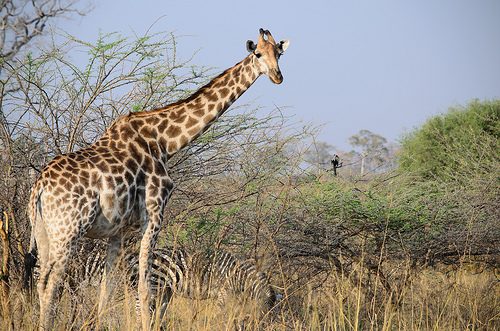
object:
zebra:
[123, 246, 282, 331]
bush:
[0, 181, 26, 290]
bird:
[331, 153, 340, 175]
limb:
[274, 222, 313, 255]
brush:
[235, 192, 485, 301]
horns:
[258, 28, 276, 44]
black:
[259, 28, 271, 36]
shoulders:
[107, 115, 166, 163]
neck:
[149, 55, 261, 151]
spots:
[187, 102, 206, 117]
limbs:
[390, 218, 458, 261]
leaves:
[439, 104, 496, 138]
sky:
[0, 0, 500, 154]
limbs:
[12, 109, 80, 167]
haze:
[310, 0, 500, 97]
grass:
[0, 314, 500, 330]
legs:
[29, 200, 167, 331]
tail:
[23, 190, 44, 302]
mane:
[127, 65, 237, 118]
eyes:
[277, 53, 281, 59]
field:
[0, 159, 500, 331]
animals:
[19, 28, 289, 331]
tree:
[348, 130, 387, 180]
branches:
[0, 0, 93, 59]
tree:
[0, 0, 98, 278]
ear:
[246, 40, 255, 53]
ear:
[277, 39, 290, 53]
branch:
[255, 156, 308, 193]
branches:
[349, 129, 389, 149]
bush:
[401, 99, 500, 252]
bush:
[156, 188, 238, 246]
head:
[246, 28, 290, 84]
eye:
[254, 51, 261, 58]